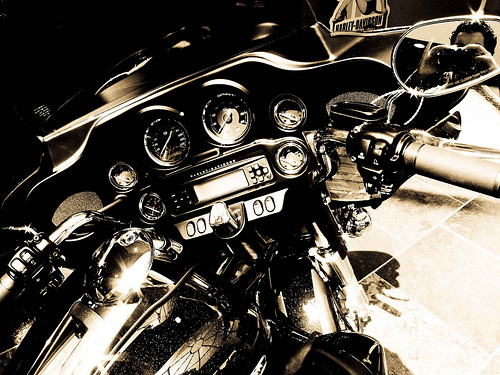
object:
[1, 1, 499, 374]
photograph is black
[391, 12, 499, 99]
rear view mirror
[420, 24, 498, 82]
man taking picture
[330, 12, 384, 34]
company logo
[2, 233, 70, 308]
handle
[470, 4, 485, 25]
sparkle of light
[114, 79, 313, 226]
control panel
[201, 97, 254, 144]
circle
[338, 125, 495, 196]
handlebar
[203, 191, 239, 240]
metal knob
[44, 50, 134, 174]
curved outer edge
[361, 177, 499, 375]
ceramic floor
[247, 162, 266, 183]
buttons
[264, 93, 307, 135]
black gauge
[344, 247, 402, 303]
shadows cast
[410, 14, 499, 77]
man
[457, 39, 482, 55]
finger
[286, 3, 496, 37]
background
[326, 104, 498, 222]
handlebars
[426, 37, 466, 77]
camera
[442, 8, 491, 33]
hair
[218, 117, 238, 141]
hands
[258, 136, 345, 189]
circle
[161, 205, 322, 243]
buttons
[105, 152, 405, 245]
control panel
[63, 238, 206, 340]
attachment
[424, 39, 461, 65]
binoculars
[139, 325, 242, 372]
spokes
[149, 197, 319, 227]
braking gear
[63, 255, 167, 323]
gas cap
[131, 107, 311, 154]
speedometer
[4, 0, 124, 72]
background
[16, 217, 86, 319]
brake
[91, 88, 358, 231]
dials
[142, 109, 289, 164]
gauge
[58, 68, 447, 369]
bike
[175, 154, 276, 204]
radio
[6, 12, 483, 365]
bike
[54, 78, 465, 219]
handle.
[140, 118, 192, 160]
speedometer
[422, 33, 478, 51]
reflection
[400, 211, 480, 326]
concrete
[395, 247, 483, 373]
ground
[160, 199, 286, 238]
buttons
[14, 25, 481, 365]
motorcycle